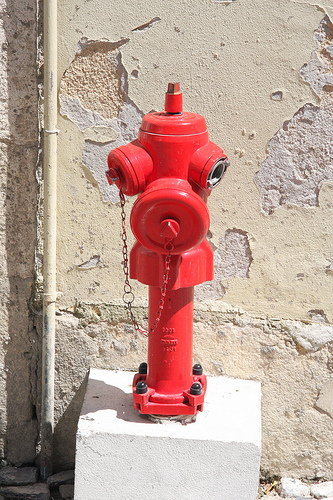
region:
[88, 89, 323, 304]
a red fire hydrant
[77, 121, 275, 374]
a fire hydrant outside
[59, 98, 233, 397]
a red fire hydrant outside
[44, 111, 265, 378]
a hydrant outside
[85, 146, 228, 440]
a fire hydrant with a chain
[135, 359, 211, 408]
Four black bolts of the hydrant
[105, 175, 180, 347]
Chain of the hydrant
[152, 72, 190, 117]
Top of the hydrant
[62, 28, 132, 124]
crack in the wall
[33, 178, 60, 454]
Metal pipe along the wall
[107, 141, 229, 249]
opening for water of the hydrant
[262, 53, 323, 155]
chipping paint on the wall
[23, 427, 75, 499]
Shadow above the rocks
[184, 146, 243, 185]
opening of the hydrant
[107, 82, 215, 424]
The hydrant is red.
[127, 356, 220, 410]
There are four bolts.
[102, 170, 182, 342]
The chain is red.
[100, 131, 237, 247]
There are three nozzles.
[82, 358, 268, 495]
The stone is white.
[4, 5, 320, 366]
The wall is cracked.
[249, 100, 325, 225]
The cracks are different colors than the walls.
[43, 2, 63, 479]
There is conduit attached to the wall.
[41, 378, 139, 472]
You can see the hydran't shadow.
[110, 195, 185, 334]
a chain on the fire hydrant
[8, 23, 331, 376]
a chipped wall behind hydrant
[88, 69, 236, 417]
hydrant on top of concrete block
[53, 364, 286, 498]
a white concrete block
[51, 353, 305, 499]
a white block under hydrant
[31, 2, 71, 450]
a white pole against the wall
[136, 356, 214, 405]
Black nuts on a hydrant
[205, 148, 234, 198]
one missing valve cover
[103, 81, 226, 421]
the fire hydrant is red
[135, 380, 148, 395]
a black bolt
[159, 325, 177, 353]
lettering on the hydrant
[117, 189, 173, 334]
a red chain on the hydrant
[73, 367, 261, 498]
a concrete base under the hydrant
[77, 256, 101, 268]
missing finish on the wall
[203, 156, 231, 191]
the cap is missing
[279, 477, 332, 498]
white rocks on the ground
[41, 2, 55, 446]
a long skinny pipe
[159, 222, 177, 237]
the bolt is triangle